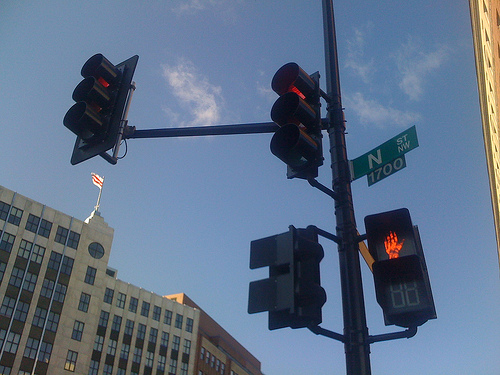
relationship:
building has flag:
[0, 182, 267, 373] [93, 170, 106, 192]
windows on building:
[103, 286, 195, 332] [0, 182, 267, 373]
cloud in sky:
[158, 53, 228, 131] [2, 2, 500, 373]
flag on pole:
[93, 170, 106, 192] [97, 192, 103, 205]